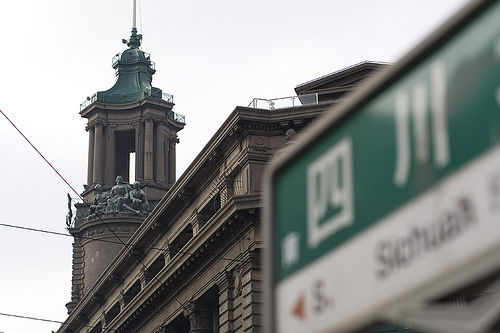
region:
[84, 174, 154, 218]
Green statues on a building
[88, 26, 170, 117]
Green roof on a tower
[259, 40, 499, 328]
Green sign with white lettering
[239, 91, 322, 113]
Glass fence around roof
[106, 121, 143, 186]
Long windows in tower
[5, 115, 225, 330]
Power lines running to buildings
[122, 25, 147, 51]
Green statue on roof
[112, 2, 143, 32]
The steeple point of the building.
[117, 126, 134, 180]
The opening of the top of the building.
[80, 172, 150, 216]
The statues on the building in front of the opening.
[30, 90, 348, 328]
The flat roof of the building.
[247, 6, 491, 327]
The street sign on the right.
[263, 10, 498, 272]
The green part of the street sign.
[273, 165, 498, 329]
The white part of the street sign.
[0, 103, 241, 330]
The cable wires in front of the building.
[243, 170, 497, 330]
The black letters on the street sign.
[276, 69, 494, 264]
The white design on the green part of the street sign.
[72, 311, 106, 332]
narrow window on building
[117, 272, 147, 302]
narrow window on building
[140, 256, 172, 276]
narrow window on building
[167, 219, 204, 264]
narrow window on building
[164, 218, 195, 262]
narrow window on building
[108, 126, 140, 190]
narrow window on building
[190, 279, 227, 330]
narrow window on building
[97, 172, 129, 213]
small statue on building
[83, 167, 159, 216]
statues on the building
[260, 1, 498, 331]
street sign is green and white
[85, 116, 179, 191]
pillars on the building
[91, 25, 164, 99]
top of the building is green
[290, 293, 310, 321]
orange arrow sign on the street sign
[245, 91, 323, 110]
railing on top of building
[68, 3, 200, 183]
copper top of building tower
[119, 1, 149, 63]
steeple copper top of building tower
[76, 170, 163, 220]
copper statue on building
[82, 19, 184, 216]
copper statue on building tower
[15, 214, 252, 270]
black electrical line by building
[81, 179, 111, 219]
statue of man on building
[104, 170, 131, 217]
statue of woman on building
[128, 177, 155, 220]
statue of man on building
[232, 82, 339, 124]
metal fence on edge of building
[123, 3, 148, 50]
Flagpole on top of tower.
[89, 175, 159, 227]
Statues on a tower.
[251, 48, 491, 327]
Blurred street sign.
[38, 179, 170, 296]
Criss crossing wires.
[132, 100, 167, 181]
Decorative columns.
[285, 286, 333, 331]
A red arrow pointing left.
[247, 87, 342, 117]
Observation deck on top of a building.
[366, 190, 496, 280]
Blurred word on a sign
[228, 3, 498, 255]
a green and white sign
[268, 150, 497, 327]
white trim on sign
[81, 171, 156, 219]
statue on a tower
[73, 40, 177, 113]
green top of tower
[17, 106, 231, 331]
a group of cables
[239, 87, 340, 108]
railing on the building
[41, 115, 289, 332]
the building is brown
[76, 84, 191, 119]
railing on the tower